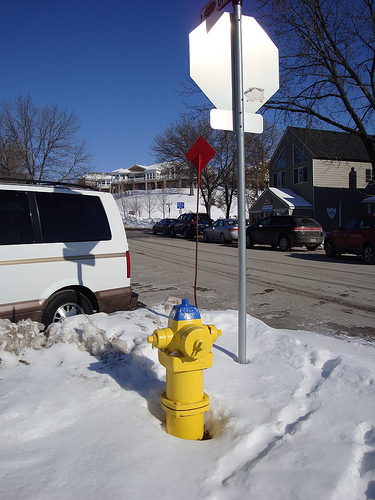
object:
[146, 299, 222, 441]
hydrant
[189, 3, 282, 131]
traffic sign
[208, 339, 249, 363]
shadow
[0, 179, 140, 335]
van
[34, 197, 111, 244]
window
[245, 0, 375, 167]
tree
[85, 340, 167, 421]
shadow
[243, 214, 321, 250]
car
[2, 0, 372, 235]
distance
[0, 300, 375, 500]
snow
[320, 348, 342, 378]
foot steps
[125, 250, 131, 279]
light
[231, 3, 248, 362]
pole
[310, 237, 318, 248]
plate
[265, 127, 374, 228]
building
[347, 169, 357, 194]
window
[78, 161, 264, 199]
building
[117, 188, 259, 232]
hill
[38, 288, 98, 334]
tire